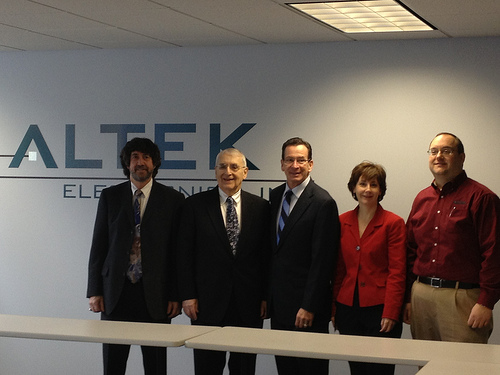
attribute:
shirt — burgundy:
[273, 174, 311, 246]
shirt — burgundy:
[215, 188, 243, 229]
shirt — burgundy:
[126, 179, 153, 221]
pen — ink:
[450, 202, 457, 214]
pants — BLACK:
[327, 296, 396, 373]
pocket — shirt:
[442, 197, 471, 227]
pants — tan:
[407, 272, 492, 341]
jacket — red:
[338, 210, 407, 322]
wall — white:
[297, 61, 413, 118]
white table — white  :
[2, 312, 499, 373]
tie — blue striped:
[273, 190, 296, 247]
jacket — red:
[334, 205, 409, 317]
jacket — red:
[330, 203, 412, 309]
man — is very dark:
[96, 140, 208, 374]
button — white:
[432, 208, 442, 214]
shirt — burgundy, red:
[396, 172, 498, 311]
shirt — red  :
[407, 177, 484, 298]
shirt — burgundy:
[402, 181, 497, 301]